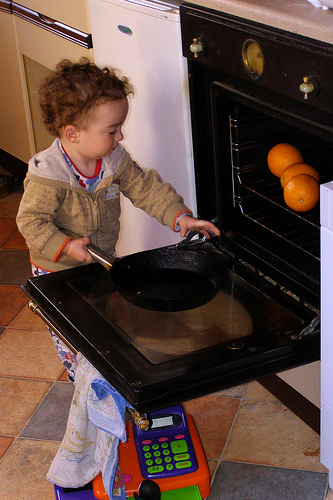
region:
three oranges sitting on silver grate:
[258, 135, 319, 211]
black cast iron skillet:
[107, 245, 226, 316]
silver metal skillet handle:
[77, 236, 115, 275]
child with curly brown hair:
[29, 53, 135, 159]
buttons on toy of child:
[138, 437, 197, 479]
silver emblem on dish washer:
[113, 18, 137, 40]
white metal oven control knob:
[183, 35, 214, 65]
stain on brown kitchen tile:
[293, 435, 319, 465]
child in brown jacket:
[8, 65, 207, 259]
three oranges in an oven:
[263, 141, 315, 211]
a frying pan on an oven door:
[83, 240, 228, 311]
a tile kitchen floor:
[1, 168, 332, 498]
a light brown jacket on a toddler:
[15, 139, 189, 271]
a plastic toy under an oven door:
[55, 400, 204, 499]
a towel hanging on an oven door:
[43, 351, 130, 498]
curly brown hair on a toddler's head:
[39, 57, 131, 136]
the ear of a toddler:
[59, 122, 79, 145]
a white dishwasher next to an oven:
[81, 0, 197, 255]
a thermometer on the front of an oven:
[241, 37, 263, 80]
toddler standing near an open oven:
[10, 48, 231, 391]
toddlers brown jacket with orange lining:
[20, 131, 196, 272]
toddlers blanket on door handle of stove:
[39, 349, 134, 499]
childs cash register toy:
[35, 402, 215, 499]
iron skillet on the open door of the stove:
[114, 215, 235, 316]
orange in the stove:
[281, 172, 320, 211]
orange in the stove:
[278, 161, 320, 184]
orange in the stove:
[264, 140, 303, 176]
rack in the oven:
[246, 177, 324, 227]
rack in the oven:
[239, 197, 319, 258]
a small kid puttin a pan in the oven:
[29, 57, 209, 268]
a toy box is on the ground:
[119, 409, 210, 497]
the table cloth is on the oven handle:
[72, 381, 142, 480]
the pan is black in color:
[120, 261, 226, 323]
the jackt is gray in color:
[26, 165, 132, 262]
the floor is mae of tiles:
[10, 364, 69, 472]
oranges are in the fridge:
[255, 143, 324, 217]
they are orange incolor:
[264, 142, 332, 220]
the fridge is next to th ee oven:
[100, 14, 210, 171]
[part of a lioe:
[155, 63, 179, 132]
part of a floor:
[230, 435, 251, 467]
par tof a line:
[226, 397, 248, 433]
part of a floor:
[263, 402, 287, 429]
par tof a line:
[167, 470, 180, 488]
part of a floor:
[258, 406, 273, 423]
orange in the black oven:
[281, 170, 318, 211]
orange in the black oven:
[280, 160, 320, 195]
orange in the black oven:
[264, 144, 304, 177]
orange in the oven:
[285, 179, 313, 203]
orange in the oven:
[281, 163, 323, 183]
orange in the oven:
[266, 136, 298, 177]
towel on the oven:
[52, 351, 128, 484]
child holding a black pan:
[53, 223, 235, 320]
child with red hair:
[34, 57, 136, 159]